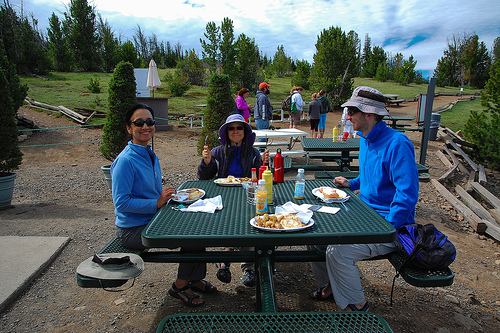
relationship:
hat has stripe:
[338, 73, 401, 125] [351, 69, 400, 112]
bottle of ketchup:
[252, 157, 269, 185] [254, 154, 275, 188]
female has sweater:
[196, 114, 262, 288] [181, 125, 280, 194]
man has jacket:
[107, 122, 172, 242] [108, 140, 165, 229]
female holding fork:
[196, 114, 262, 288] [190, 120, 224, 180]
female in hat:
[196, 114, 262, 288] [207, 101, 264, 148]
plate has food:
[227, 188, 320, 249] [250, 206, 308, 226]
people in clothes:
[97, 73, 421, 250] [97, 89, 432, 252]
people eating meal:
[97, 73, 421, 250] [166, 167, 353, 252]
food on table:
[250, 206, 308, 226] [104, 150, 420, 331]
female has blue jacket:
[196, 114, 262, 288] [181, 125, 280, 194]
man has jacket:
[107, 122, 172, 242] [89, 135, 186, 233]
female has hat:
[196, 114, 262, 288] [207, 101, 264, 148]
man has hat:
[248, 73, 284, 130] [252, 77, 277, 97]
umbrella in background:
[114, 48, 185, 124] [2, 0, 494, 188]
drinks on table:
[262, 139, 320, 203] [104, 150, 420, 331]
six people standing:
[219, 64, 363, 149] [222, 62, 363, 148]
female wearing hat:
[196, 114, 262, 288] [207, 101, 264, 148]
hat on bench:
[58, 238, 161, 311] [64, 196, 188, 300]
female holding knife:
[196, 114, 262, 288] [254, 135, 284, 192]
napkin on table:
[181, 181, 235, 223] [104, 150, 420, 331]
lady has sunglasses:
[180, 101, 277, 198] [214, 115, 257, 136]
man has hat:
[308, 85, 420, 313] [338, 73, 401, 125]